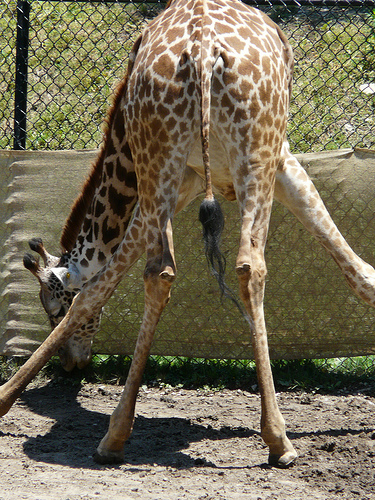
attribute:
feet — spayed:
[2, 338, 308, 476]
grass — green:
[156, 356, 259, 381]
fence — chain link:
[3, 2, 362, 381]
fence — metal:
[2, 2, 359, 147]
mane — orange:
[50, 55, 135, 259]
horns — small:
[16, 234, 52, 272]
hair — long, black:
[204, 199, 253, 320]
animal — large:
[3, 4, 373, 460]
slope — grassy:
[0, 1, 373, 389]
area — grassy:
[4, 7, 373, 383]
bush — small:
[348, 20, 373, 84]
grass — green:
[91, 353, 373, 394]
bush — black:
[199, 200, 254, 329]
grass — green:
[89, 352, 374, 399]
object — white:
[327, 357, 347, 369]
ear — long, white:
[49, 265, 82, 290]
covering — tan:
[1, 146, 373, 358]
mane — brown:
[58, 74, 126, 249]